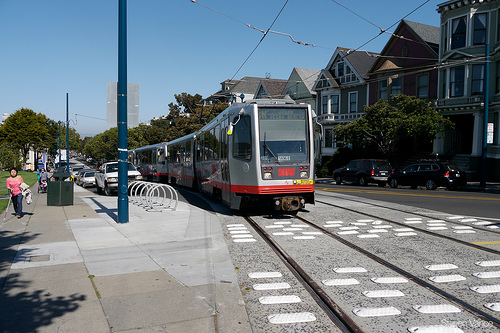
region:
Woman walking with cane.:
[0, 161, 43, 233]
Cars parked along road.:
[314, 121, 499, 198]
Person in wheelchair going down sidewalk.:
[27, 151, 54, 198]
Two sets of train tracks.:
[251, 190, 497, 332]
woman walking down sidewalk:
[7, 166, 32, 211]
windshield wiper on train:
[257, 129, 275, 159]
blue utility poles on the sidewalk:
[59, 5, 139, 220]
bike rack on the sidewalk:
[129, 174, 174, 214]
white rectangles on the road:
[227, 207, 497, 332]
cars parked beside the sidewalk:
[70, 153, 136, 200]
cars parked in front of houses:
[324, 152, 461, 191]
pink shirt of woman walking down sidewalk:
[6, 179, 26, 196]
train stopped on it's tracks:
[130, 101, 315, 212]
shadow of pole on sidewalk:
[83, 191, 123, 231]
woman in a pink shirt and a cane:
[4, 166, 31, 216]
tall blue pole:
[114, 2, 129, 222]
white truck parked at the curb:
[96, 160, 141, 193]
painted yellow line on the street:
[321, 185, 498, 202]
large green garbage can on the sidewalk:
[48, 170, 74, 205]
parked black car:
[388, 157, 468, 191]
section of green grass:
[2, 169, 37, 213]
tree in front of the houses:
[333, 91, 455, 166]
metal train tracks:
[244, 210, 494, 328]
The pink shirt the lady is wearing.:
[5, 174, 22, 193]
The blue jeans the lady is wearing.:
[10, 197, 22, 214]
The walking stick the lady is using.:
[0, 197, 12, 229]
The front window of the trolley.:
[260, 109, 311, 181]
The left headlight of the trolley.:
[261, 171, 272, 179]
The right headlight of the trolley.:
[300, 171, 309, 176]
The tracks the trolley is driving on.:
[252, 214, 499, 331]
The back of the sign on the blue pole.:
[109, 84, 137, 130]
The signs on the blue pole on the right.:
[486, 125, 493, 144]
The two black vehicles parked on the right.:
[332, 158, 467, 190]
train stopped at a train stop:
[137, 99, 310, 209]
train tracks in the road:
[265, 179, 497, 331]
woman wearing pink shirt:
[3, 166, 33, 211]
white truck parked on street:
[99, 157, 136, 189]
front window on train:
[255, 109, 305, 146]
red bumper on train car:
[232, 179, 311, 195]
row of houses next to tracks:
[210, 5, 499, 182]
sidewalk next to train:
[10, 169, 235, 332]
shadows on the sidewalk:
[3, 222, 78, 332]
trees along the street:
[9, 79, 443, 194]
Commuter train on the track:
[127, 96, 317, 214]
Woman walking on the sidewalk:
[5, 164, 28, 217]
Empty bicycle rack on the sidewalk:
[126, 177, 178, 216]